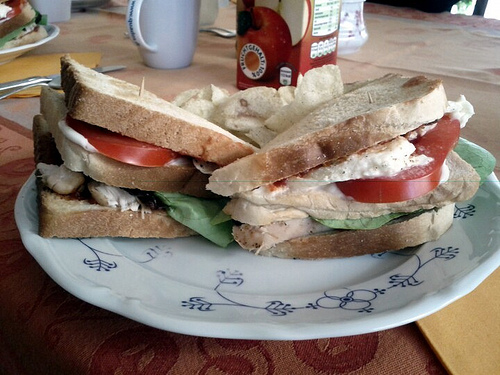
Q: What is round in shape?
A: The plate.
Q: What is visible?
A: Bread.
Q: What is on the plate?
A: Food.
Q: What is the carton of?
A: Apple juice.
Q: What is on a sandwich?
A: Tomato slices.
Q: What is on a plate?
A: Food.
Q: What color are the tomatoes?
A: Red.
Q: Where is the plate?
A: On the table.